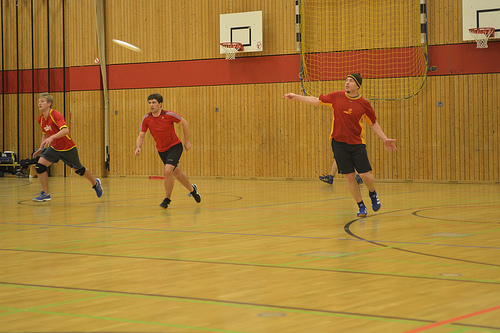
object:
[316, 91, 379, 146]
shirt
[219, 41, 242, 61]
basketball hoop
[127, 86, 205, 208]
men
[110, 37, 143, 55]
frisbee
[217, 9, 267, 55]
backboard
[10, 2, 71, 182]
beams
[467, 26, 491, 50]
hoop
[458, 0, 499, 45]
backboard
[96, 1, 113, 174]
curtain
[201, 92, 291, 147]
wood wall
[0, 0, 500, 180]
paneled wall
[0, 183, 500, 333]
court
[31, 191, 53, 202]
sneakers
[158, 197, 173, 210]
shoes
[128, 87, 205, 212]
player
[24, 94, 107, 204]
man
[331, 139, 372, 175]
shorts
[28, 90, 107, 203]
players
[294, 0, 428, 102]
net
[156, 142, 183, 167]
shorts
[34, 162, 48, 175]
knee pads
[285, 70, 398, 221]
man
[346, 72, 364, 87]
cap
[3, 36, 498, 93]
line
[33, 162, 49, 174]
guards